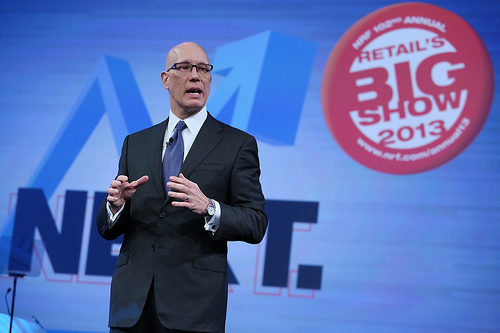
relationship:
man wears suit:
[95, 41, 270, 333] [95, 105, 272, 333]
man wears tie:
[95, 41, 270, 333] [160, 120, 188, 198]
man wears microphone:
[95, 41, 270, 333] [166, 136, 176, 147]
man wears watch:
[95, 41, 270, 333] [204, 197, 217, 227]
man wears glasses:
[95, 41, 270, 333] [165, 61, 213, 75]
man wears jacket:
[95, 41, 270, 333] [95, 109, 268, 332]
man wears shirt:
[95, 41, 270, 333] [104, 106, 221, 238]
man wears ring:
[95, 41, 270, 333] [186, 195, 192, 201]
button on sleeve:
[212, 223, 218, 231] [203, 198, 220, 235]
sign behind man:
[320, 2, 497, 177] [95, 41, 270, 333]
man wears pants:
[95, 41, 270, 333] [108, 275, 197, 333]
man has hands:
[95, 41, 270, 333] [106, 171, 207, 219]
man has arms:
[95, 41, 270, 333] [97, 134, 269, 245]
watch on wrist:
[204, 197, 217, 227] [203, 198, 218, 219]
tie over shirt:
[160, 120, 188, 198] [104, 106, 221, 238]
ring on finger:
[186, 195, 192, 201] [168, 189, 195, 202]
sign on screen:
[320, 2, 497, 177] [0, 1, 500, 331]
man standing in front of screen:
[95, 41, 270, 333] [0, 1, 500, 331]